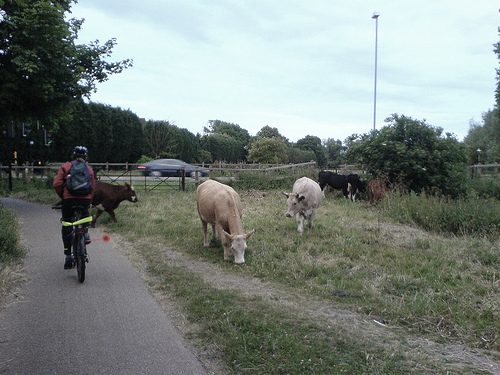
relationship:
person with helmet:
[53, 144, 95, 269] [69, 142, 90, 158]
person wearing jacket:
[53, 144, 95, 269] [49, 155, 98, 202]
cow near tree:
[317, 171, 369, 204] [340, 112, 471, 201]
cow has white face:
[193, 176, 255, 266] [228, 236, 250, 265]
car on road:
[134, 154, 214, 177] [1, 169, 318, 186]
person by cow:
[53, 144, 95, 269] [55, 177, 141, 230]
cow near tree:
[317, 171, 369, 204] [337, 111, 478, 211]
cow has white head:
[193, 176, 255, 266] [222, 228, 257, 266]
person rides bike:
[53, 144, 95, 269] [47, 200, 99, 285]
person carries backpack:
[53, 144, 95, 269] [65, 157, 94, 195]